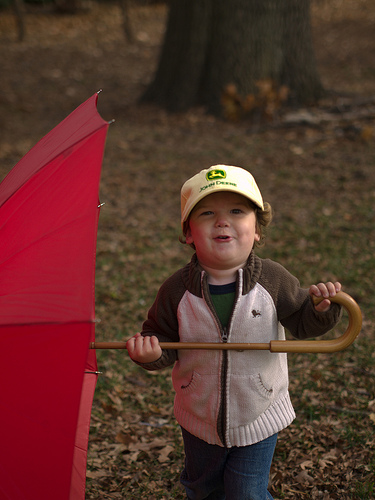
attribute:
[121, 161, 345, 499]
boy — little, young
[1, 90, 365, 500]
umbrella — red, held, sideways, large, open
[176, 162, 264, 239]
hat — john deere hat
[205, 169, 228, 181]
deer — yellow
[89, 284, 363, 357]
handle — wood, brown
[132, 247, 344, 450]
sweater — brown, white, off white, zipped up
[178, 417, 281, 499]
jeans — blue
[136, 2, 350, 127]
tree trunk — brown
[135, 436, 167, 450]
leaf — brown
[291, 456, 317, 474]
leaf — brown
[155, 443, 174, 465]
leaf — brown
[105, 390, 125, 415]
leaf — brown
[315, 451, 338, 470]
leaf — brown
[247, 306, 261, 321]
design — small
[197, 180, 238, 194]
text — green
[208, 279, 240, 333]
shirt — green